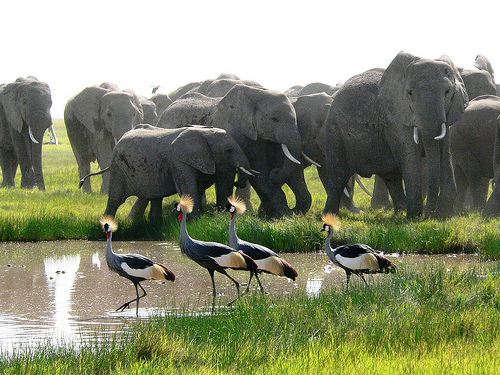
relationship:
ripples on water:
[1, 313, 135, 349] [0, 237, 497, 363]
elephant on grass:
[79, 122, 261, 225] [319, 294, 447, 365]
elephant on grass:
[163, 64, 315, 204] [319, 294, 447, 365]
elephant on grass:
[300, 32, 455, 218] [319, 294, 447, 365]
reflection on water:
[38, 249, 85, 348] [2, 238, 239, 356]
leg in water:
[123, 286, 145, 318] [50, 274, 150, 335]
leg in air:
[109, 283, 143, 320] [61, 212, 145, 330]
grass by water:
[114, 309, 368, 363] [25, 245, 97, 325]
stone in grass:
[116, 332, 156, 364] [114, 309, 368, 363]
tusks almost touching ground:
[339, 180, 351, 201] [257, 200, 430, 260]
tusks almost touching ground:
[352, 171, 376, 196] [257, 200, 430, 260]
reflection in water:
[38, 249, 85, 348] [5, 276, 103, 336]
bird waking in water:
[99, 215, 177, 318] [0, 237, 497, 363]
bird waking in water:
[170, 194, 260, 316] [0, 237, 497, 363]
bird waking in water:
[225, 195, 298, 299] [0, 237, 497, 363]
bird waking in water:
[320, 222, 398, 295] [0, 237, 497, 363]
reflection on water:
[42, 250, 79, 342] [0, 237, 497, 363]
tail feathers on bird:
[374, 256, 396, 276] [318, 212, 400, 294]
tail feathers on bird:
[158, 264, 175, 284] [99, 215, 177, 318]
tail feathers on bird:
[237, 252, 257, 272] [170, 194, 259, 315]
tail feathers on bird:
[280, 264, 297, 281] [223, 191, 300, 306]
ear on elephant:
[169, 127, 220, 179] [78, 121, 254, 225]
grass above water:
[49, 205, 474, 248] [48, 256, 82, 321]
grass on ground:
[163, 262, 498, 353] [0, 124, 496, 371]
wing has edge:
[180, 232, 254, 270] [210, 249, 224, 261]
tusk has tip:
[280, 142, 301, 165] [292, 153, 304, 167]